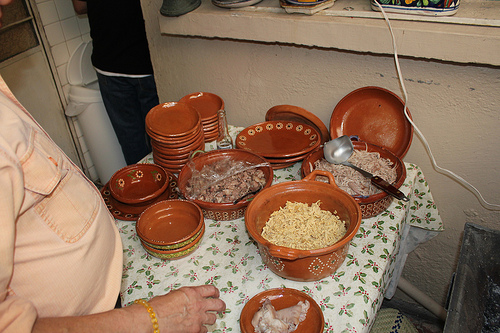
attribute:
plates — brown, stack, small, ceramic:
[143, 98, 208, 172]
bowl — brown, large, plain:
[242, 168, 362, 289]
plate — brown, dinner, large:
[234, 116, 321, 161]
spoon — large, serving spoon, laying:
[322, 133, 411, 203]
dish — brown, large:
[180, 150, 266, 223]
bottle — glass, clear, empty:
[214, 108, 235, 147]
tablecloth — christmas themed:
[110, 123, 446, 331]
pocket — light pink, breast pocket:
[9, 126, 104, 243]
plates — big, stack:
[235, 115, 322, 174]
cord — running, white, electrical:
[375, 0, 500, 219]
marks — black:
[401, 76, 481, 96]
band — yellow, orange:
[135, 297, 162, 332]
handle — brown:
[371, 176, 407, 206]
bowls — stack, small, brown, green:
[131, 197, 208, 261]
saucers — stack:
[180, 91, 228, 142]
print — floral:
[129, 170, 146, 182]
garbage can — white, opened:
[57, 41, 131, 189]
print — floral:
[206, 243, 259, 289]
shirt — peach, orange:
[0, 76, 120, 331]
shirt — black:
[85, 1, 156, 75]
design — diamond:
[306, 257, 341, 277]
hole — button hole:
[47, 155, 60, 170]